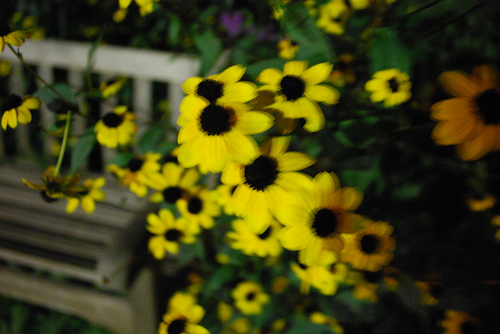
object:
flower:
[99, 74, 129, 99]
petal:
[202, 134, 227, 174]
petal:
[223, 130, 261, 166]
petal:
[236, 110, 275, 135]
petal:
[177, 122, 200, 145]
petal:
[178, 143, 198, 168]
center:
[199, 104, 237, 136]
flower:
[143, 161, 202, 203]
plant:
[0, 0, 499, 334]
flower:
[429, 71, 500, 162]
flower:
[365, 67, 414, 109]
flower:
[255, 59, 341, 133]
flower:
[179, 63, 260, 116]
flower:
[176, 94, 275, 175]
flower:
[1, 90, 43, 130]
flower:
[0, 13, 46, 50]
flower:
[63, 175, 108, 214]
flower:
[118, 149, 161, 187]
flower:
[174, 184, 221, 234]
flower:
[145, 207, 202, 259]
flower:
[229, 281, 271, 315]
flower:
[226, 215, 285, 258]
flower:
[156, 291, 208, 333]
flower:
[438, 309, 500, 333]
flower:
[93, 105, 138, 150]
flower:
[336, 219, 396, 273]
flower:
[268, 171, 363, 266]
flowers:
[220, 136, 318, 236]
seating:
[0, 38, 217, 334]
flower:
[21, 165, 87, 203]